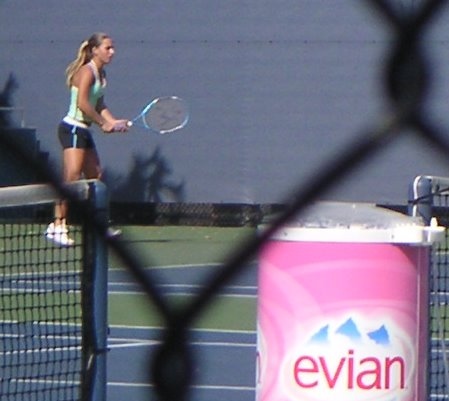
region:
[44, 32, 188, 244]
The person is playing tennis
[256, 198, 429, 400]
Evian container is pink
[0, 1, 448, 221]
Back wall is blue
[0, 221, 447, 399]
Tennis courts are blue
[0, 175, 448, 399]
Tennis nets separate courts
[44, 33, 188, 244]
The player is holding rackets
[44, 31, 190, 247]
The player is wearing shorts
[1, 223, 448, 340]
The courts are surrounded by green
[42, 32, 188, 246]
The player is wearing green shirt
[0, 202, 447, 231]
Wall has black bottom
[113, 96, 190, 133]
a tennis racket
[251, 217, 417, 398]
a pink cup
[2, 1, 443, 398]
a wire fence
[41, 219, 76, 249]
a white shoe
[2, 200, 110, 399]
a net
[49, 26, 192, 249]
a woman holding a racket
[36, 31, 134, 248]
a woman wearing shorts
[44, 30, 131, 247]
a woman with long hair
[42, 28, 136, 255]
a woman wearing a blue top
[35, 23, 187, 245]
a woman playing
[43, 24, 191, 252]
woman playing tennis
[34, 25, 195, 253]
woman preparing to hit tennis ball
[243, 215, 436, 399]
pink Evian trash can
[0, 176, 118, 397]
net at a tennis court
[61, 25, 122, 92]
blonde woman with a ponytail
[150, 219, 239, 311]
blue tennis court with green surround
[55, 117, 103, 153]
navy blue shorts with light blue stripe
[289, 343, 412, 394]
logo for Evian on trash can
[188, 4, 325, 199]
grey barrier cloth at tennis court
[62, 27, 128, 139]
blonde woman wearing green shirt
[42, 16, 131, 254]
Blond tennis player with a green shirt.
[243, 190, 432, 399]
Evian water cooler.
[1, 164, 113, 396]
Tennis net on the court.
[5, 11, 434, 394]
Photo taken during the day.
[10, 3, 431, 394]
Photographer is behind chain link fence.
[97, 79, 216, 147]
Tennis racket in woman's hands.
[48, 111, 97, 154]
Blue shorts on tennis player.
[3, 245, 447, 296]
Blue tennis court.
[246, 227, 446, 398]
Evian cooler is primarily pink.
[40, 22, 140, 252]
Tennis player is a blond woman.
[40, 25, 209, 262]
A woman is playing tennis.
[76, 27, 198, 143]
The woman is holding a blue tennis racket.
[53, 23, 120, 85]
The woman has her hair in a ponytail.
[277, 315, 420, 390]
The logo for Evian water.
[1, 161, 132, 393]
The net.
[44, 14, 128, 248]
The woman is wearing a light green tank top.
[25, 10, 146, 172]
The woman is wearing black shorts.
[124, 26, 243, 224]
A blue tarp over a chain-link fence.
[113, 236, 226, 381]
The court is green and blue.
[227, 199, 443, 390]
An upright cooler for water bottles.